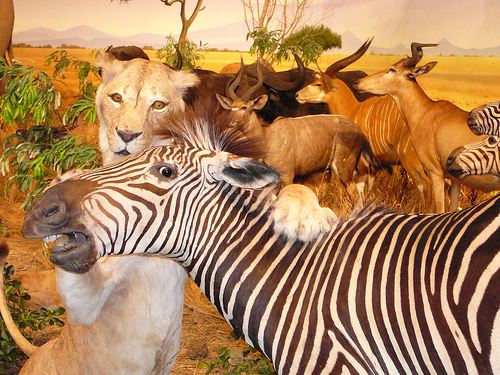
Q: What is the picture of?
A: Wild animals.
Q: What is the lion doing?
A: Killing the zebra.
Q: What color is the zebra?
A: Black and white.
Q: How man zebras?
A: 3.